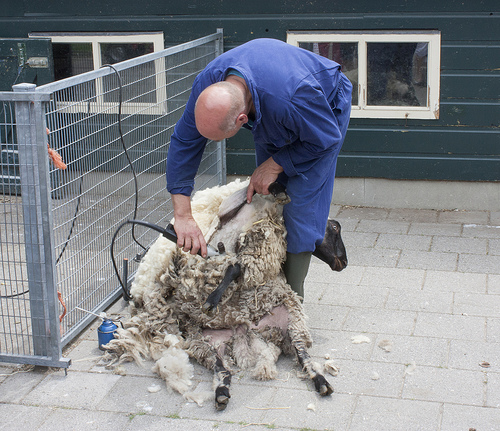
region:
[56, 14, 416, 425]
a bald man in a blue coat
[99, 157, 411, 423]
a sheep getting it coat cut off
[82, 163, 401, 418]
a sheep getting its coat sheered off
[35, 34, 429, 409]
a man harvesting wool.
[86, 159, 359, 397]
buzzers used to shear a sheep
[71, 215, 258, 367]
oil to keep buzzers smooth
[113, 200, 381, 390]
a sheep's head between a man's legs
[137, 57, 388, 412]
man holding a sheeps leg to shave him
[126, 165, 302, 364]
wool being shaved off a sheep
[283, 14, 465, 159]
window on a green building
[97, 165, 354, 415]
sheep on ground being shorn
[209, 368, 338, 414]
sheep hooves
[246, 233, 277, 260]
sheep fur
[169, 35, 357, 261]
man in blue uniform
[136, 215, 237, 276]
black and silver hair clipper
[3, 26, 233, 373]
metal fence on side of green building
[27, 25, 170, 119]
white framed window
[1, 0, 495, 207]
green building with white framed window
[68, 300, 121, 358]
blue can on ground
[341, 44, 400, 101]
reflection of man in window glass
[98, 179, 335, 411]
A sheep being sheared.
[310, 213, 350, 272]
A black sheep head.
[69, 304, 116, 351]
A small blue oil can.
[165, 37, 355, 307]
A man in a blue coat.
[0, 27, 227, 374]
A gray metal fence.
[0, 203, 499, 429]
A gray paved area.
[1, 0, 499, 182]
A dark green wall.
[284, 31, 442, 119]
A white framed window.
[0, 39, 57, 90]
Part of a green gate.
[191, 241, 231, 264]
Some industrial sized clippers.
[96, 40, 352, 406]
A sheep being shorn .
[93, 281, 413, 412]
Sheep wool on the ground.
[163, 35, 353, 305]
A sheep shearer dressed in blue.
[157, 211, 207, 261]
The shearer's hand holding an electric shear.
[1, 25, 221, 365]
A metal wire lined fence.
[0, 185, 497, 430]
Ground is paved with paver stones.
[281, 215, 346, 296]
The shearer is wearing black boots.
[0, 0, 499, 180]
A green building behind the shearer.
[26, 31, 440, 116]
Two windows with white frames.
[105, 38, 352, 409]
A sheep shearer shearing a fluffy sheep.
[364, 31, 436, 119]
a window of a building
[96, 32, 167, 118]
a window of a building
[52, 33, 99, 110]
a window of a building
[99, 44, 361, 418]
a man sheering a sheep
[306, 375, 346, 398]
the hoof of a sheep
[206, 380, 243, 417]
the hoof of a sheep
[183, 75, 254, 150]
the bald head of a man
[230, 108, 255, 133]
the ear of a man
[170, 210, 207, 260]
the hand of a man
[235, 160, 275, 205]
the hand of a man